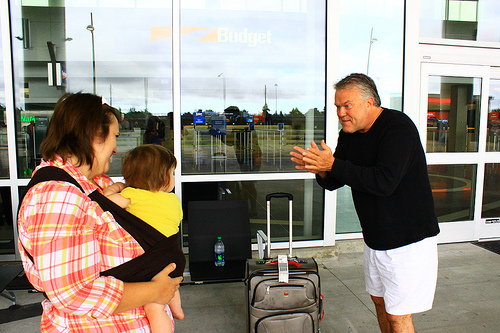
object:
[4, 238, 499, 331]
cement floor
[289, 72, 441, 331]
man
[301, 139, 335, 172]
hand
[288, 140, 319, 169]
hand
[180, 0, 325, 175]
glass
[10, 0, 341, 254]
door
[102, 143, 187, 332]
baby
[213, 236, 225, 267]
bottle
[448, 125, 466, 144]
ground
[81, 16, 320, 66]
clouds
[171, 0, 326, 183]
windows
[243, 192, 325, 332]
luggage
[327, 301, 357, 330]
ground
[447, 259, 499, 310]
ground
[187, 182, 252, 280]
bag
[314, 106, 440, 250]
shirt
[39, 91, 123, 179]
head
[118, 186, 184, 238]
shirt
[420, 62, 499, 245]
door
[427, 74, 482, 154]
panel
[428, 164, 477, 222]
panel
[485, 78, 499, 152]
panel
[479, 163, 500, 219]
panel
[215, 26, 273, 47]
name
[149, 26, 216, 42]
logo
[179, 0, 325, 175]
window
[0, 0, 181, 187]
window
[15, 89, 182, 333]
mom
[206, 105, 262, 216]
reflection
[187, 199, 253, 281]
object